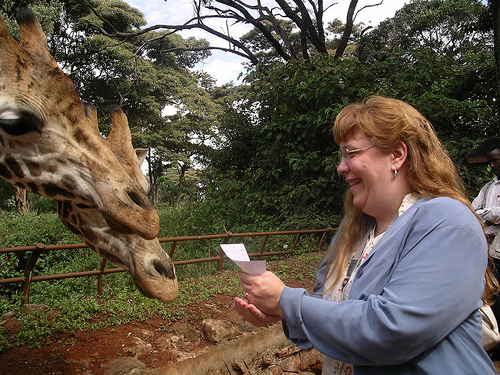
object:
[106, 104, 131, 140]
horn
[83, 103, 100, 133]
horn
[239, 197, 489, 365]
arm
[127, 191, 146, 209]
nostril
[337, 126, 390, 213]
face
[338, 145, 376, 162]
glasses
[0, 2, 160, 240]
heads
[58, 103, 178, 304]
heads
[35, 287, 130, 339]
house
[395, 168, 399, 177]
earring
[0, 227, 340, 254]
pole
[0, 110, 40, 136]
eye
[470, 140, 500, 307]
man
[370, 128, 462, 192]
ground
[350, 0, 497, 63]
trees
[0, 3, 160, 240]
giraffe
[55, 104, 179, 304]
giraffe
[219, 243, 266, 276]
paper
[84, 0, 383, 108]
tall tree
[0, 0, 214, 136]
tall tree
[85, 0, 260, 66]
branches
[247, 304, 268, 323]
finger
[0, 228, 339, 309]
fence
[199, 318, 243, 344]
rock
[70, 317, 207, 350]
dirt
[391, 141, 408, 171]
ear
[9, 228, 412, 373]
ground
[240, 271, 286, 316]
hand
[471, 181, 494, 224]
arms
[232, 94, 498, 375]
woman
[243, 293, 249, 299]
ring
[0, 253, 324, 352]
grass